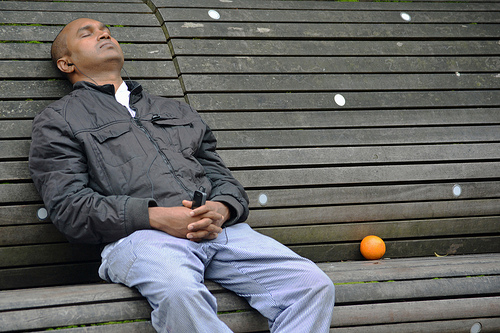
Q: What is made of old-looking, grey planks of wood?
A: A large, bench.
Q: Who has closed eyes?
A: A man, wearing blue pants, leaning back, on a bench.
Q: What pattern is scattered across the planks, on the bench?
A: Round, blue and white circles.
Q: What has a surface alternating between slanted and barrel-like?
A: A large, grey bench.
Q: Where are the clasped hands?
A: On the lap of the man, on the bench.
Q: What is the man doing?
A: Sitting on a bench.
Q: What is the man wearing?
A: Blue jeans.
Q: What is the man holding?
A: A phone.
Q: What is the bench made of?
A: Wood.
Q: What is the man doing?
A: Sleeping.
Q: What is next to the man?
A: An orange.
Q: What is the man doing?
A: Leaning back.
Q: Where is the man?
A: Resting on a bench.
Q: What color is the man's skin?
A: Brown.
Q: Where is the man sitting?
A: Bench.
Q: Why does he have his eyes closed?
A: He is sleeping.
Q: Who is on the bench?
A: The man.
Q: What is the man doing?
A: Resting.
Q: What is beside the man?
A: An orange.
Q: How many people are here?
A: 1.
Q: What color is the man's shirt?
A: Grey.